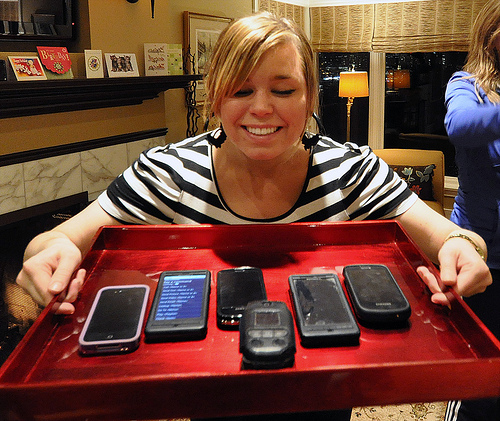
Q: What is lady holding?
A: A tray.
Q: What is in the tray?
A: Mobile phones.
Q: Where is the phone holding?
A: On a red tray.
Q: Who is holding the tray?
A: A lady.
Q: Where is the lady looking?
A: On the tray.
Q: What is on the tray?
A: Cell phones.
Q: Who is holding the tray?
A: A woman.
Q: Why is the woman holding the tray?
A: To hold the phones.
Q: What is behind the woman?
A: A fireplace.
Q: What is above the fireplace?
A: A shelf.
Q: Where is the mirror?
A: Above the shelf.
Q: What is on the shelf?
A: Cards.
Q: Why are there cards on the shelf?
A: Decoration.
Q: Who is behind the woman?
A: Another woman.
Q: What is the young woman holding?
A: The young woman is holding a tray of cell phones.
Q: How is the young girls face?
A: The young girls face is smiling with eyes closed.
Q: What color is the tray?
A: Red.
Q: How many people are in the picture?
A: Two.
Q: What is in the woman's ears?
A: Earrings.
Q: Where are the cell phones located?
A: On the tray.